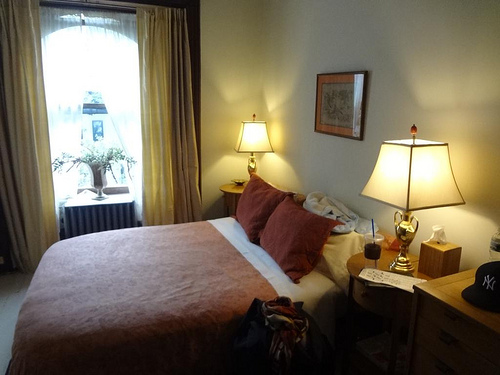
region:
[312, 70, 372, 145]
Framed artwork on the wall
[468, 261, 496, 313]
New york yankees baseball cap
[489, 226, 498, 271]
A bottle of water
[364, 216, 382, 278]
A plastic thermos with straw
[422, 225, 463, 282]
A box of tissues on the night stand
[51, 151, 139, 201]
Flowers in a vase by the window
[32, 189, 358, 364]
A luxurious looking bed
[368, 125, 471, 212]
The near lamp shade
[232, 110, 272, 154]
The far lamp shade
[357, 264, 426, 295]
A newspaper on the night stand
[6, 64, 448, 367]
a bedroom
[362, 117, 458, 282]
a lamp shade next to the bed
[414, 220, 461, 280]
a box of tissue next to the lamp shade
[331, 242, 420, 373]
a side table next to the bed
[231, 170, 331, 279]
two pillows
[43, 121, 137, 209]
a flower vase with flowers by the window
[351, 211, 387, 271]
a plastic cup with straw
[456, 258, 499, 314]
a baseball hat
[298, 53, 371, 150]
a frame hanging on the wall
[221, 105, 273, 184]
a lamp shade with a brass stand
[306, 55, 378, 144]
Framed artwork on a wall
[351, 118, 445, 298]
A brass table lamp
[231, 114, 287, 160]
A white lamp shade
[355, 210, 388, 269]
A drink with a dark blue straw in it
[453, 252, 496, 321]
A New York Yankees cap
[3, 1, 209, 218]
Curtains and sheers at a window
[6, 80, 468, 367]
A neat bedroom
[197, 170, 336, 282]
Two pillows on a bed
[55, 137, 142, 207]
A flower arrangement in front of a window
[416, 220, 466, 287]
A box of tissues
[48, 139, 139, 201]
plant in front of window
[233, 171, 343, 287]
two red pillows on bed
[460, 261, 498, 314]
black Yankees hat on dresser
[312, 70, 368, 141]
picture on wall above bed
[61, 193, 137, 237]
radiator in front of window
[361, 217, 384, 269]
drink on nightstand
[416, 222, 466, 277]
tissue box on nightstand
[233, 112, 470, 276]
two lamps turned on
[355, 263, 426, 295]
paper on nightstand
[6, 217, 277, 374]
burgundy bed spread on bed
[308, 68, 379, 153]
the painting on the wall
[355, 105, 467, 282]
the lamp next to the tissue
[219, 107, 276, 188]
the lamp near the window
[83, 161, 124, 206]
the urn in the window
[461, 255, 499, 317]
the Yankees baseball cap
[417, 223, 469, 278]
the gold tissue box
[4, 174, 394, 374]
the bed with two pillows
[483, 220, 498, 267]
the water bottle next to the cap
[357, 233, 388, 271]
the cup with the straw in it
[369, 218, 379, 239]
the blue straw in a cup